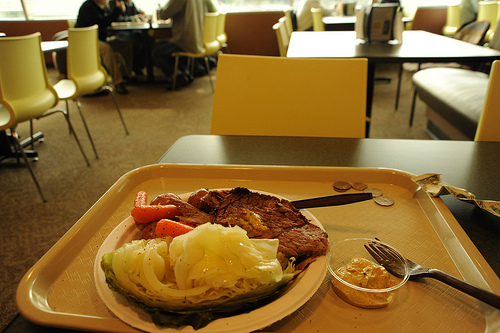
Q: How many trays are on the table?
A: 1.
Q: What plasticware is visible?
A: Knife and fork.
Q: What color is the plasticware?
A: Black.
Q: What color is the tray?
A: Tan.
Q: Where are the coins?
A: On the tray.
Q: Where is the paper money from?
A: United States.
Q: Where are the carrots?
A: Plate.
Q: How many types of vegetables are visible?
A: 2.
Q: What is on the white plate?
A: Food.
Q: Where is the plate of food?
A: On a tray.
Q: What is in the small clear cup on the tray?
A: Sauce.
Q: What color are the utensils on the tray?
A: Black.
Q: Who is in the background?
A: People eating food.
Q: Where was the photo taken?
A: In a restaurant.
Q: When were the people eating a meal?
A: During daylight hours.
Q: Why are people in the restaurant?
A: To eat a meal.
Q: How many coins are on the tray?
A: Five.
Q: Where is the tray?
A: On a table.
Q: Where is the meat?
A: On paper plate.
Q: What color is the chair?
A: Yellow.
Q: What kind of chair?
A: Metal.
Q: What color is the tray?
A: Yellow.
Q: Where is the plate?
A: On the tray.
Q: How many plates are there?
A: One.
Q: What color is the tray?
A: Yellow.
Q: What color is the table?
A: Brown.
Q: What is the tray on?
A: The table.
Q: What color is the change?
A: Silver and brown.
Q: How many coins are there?
A: Four.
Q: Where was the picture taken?
A: At a cafeteria.